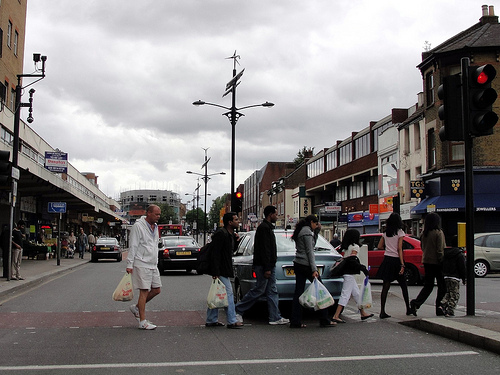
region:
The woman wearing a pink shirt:
[375, 210, 417, 320]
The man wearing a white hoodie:
[115, 201, 164, 333]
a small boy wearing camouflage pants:
[435, 236, 468, 318]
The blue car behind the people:
[223, 225, 350, 320]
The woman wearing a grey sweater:
[285, 213, 340, 330]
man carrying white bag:
[120, 185, 172, 325]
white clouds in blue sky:
[137, 39, 174, 73]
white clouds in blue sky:
[252, 13, 340, 73]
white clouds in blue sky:
[110, 39, 195, 90]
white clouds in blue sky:
[115, 101, 150, 148]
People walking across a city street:
[1, 146, 499, 356]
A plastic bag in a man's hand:
[111, 269, 136, 304]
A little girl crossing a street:
[331, 229, 376, 325]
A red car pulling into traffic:
[338, 232, 431, 283]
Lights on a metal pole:
[185, 50, 279, 237]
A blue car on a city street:
[211, 228, 364, 314]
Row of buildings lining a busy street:
[238, 141, 497, 282]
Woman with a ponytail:
[288, 213, 331, 323]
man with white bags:
[117, 202, 161, 329]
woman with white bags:
[290, 206, 338, 323]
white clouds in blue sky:
[105, 96, 129, 130]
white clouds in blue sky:
[114, 25, 156, 63]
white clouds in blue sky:
[301, 62, 333, 92]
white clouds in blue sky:
[340, 35, 390, 73]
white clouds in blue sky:
[271, 23, 318, 65]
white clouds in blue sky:
[128, 49, 169, 76]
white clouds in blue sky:
[62, 66, 119, 108]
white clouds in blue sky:
[102, 88, 142, 128]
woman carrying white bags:
[292, 212, 326, 307]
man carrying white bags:
[121, 195, 158, 315]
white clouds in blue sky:
[85, 83, 135, 115]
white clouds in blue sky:
[138, 116, 195, 161]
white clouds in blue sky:
[120, 11, 182, 75]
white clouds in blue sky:
[255, 18, 302, 58]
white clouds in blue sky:
[284, 79, 315, 111]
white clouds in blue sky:
[324, 36, 388, 90]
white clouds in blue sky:
[275, 8, 327, 55]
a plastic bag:
[208, 285, 228, 307]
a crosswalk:
[71, 307, 111, 327]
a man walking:
[125, 200, 175, 336]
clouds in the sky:
[288, 63, 351, 100]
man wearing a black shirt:
[256, 215, 281, 285]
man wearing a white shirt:
[119, 218, 163, 268]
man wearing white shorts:
[128, 262, 167, 294]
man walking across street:
[95, 190, 182, 353]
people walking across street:
[204, 198, 464, 355]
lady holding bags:
[296, 260, 337, 321]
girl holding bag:
[331, 225, 393, 342]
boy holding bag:
[183, 197, 249, 337]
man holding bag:
[96, 182, 173, 330]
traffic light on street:
[424, 31, 499, 336]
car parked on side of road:
[83, 230, 130, 280]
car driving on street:
[141, 224, 213, 316]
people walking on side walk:
[31, 222, 118, 274]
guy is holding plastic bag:
[126, 200, 164, 329]